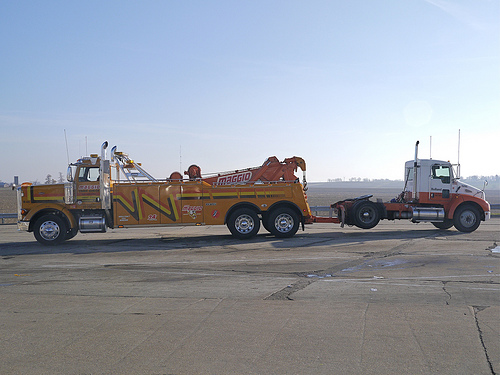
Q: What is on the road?
A: Truck.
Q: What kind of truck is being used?
A: Tow truck.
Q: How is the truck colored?
A: Orange yellow and black.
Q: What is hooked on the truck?
A: Cab.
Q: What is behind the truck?
A: A cab.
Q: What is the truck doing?
A: Working.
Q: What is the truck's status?
A: Parked.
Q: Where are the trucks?
A: On the pavement.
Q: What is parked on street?
A: A tow truck.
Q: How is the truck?
A: Red and white.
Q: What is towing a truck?
A: A tow truck.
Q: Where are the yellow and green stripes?
A: A tow truck.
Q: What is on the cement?
A: An orange truck.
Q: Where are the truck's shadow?
A: On the ground.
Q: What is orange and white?
A: A truck.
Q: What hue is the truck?
A: Orange.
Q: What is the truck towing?
A: The other truck.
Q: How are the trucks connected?
A: Trucks are hook together.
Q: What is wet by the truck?
A: The ground.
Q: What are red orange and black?
A: The lines on the tow truck.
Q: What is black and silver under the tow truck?
A: The tires of the tow truck.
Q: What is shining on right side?
A: Sun.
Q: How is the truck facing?
A: Left.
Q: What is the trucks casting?
A: A shadow.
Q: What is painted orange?
A: The truck.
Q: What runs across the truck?
A: Stripes.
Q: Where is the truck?
A: Behind the tow truck.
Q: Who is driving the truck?
A: No one.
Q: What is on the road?
A: A truck.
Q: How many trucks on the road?
A: One.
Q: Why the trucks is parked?
A: Loading.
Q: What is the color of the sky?
A: Blue.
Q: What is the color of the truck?
A: Orange.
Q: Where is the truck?
A: On the road.